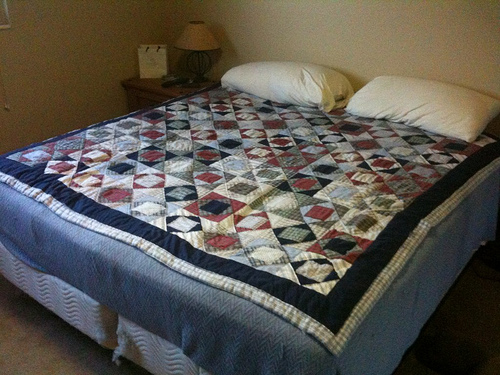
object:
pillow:
[342, 72, 500, 144]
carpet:
[1, 272, 159, 373]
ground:
[318, 177, 360, 207]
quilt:
[4, 45, 497, 375]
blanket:
[1, 85, 497, 370]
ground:
[386, 132, 432, 169]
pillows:
[219, 57, 356, 113]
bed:
[1, 52, 499, 373]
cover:
[121, 80, 421, 271]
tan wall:
[169, 0, 497, 150]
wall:
[33, 7, 103, 107]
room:
[3, 0, 500, 375]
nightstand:
[116, 64, 220, 113]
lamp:
[169, 18, 224, 83]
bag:
[135, 42, 169, 79]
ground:
[3, 290, 95, 369]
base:
[185, 50, 213, 83]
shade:
[174, 20, 235, 58]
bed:
[3, 58, 499, 374]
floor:
[6, 296, 118, 372]